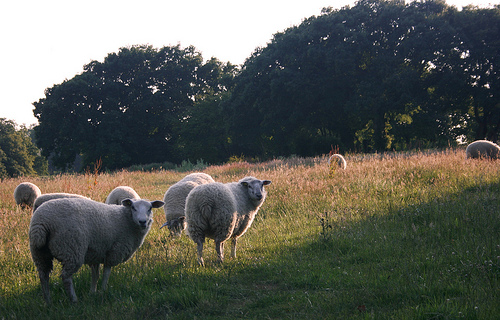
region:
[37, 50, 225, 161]
A big tree in a field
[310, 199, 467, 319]
Grass in a field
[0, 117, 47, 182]
A bush in a field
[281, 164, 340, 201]
Weeds in a field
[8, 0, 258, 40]
The sky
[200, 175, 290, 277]
A sheep in the field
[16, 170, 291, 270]
A group of sheep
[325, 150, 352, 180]
A sheep running towards tree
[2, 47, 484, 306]
A flock of sheep in a field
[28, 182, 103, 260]
Fur of a sheep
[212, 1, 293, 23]
clear blue skies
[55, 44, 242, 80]
top of green trees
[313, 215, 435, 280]
large area of shadows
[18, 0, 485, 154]
large cluster of trees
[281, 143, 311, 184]
single blades of brown grass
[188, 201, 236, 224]
small stubbly sheep's tail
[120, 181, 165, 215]
black oblong sheep's ears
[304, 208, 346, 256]
small flower patch with buds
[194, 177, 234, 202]
luxurious wool on sheep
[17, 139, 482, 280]
field with white sheep grazing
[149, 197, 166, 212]
the ear of a sheep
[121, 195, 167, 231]
the head of a sheep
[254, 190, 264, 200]
the nose of a sheep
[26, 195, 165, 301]
a sheep in the grass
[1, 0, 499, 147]
a gray sky over the field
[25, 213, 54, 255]
the tail of a sheep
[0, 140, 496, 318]
a green grassy field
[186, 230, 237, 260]
the legs of a sheep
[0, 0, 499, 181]
a row of green trees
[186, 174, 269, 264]
a sheep in the field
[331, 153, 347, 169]
Male sheep walking in a field.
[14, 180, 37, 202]
Baby sheep walking in a field.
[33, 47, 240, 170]
Large tree in a field.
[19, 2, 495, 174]
Wooded area in front of a field.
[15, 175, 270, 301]
Family of sheep walking in a field.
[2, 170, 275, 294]
Group of sheep grazing in a field.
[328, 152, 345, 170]
Lone sheep walking in a field.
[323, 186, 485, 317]
Grassy area in a field.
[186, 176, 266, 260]
Large sheep walking with the pack.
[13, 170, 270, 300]
Family of sheep eating together.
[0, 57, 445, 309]
sheep in a field of grass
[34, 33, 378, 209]
trees behind a herd of sheep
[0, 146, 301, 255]
five sheet enjoying a field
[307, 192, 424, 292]
shadowy green grass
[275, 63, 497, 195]
grazing sheep in field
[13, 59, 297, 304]
sheep looking at the camera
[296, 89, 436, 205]
field of tall grass with sheep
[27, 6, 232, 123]
bright white sky through the trees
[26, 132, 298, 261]
sheep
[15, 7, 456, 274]
herd of sheep enjoying a meal